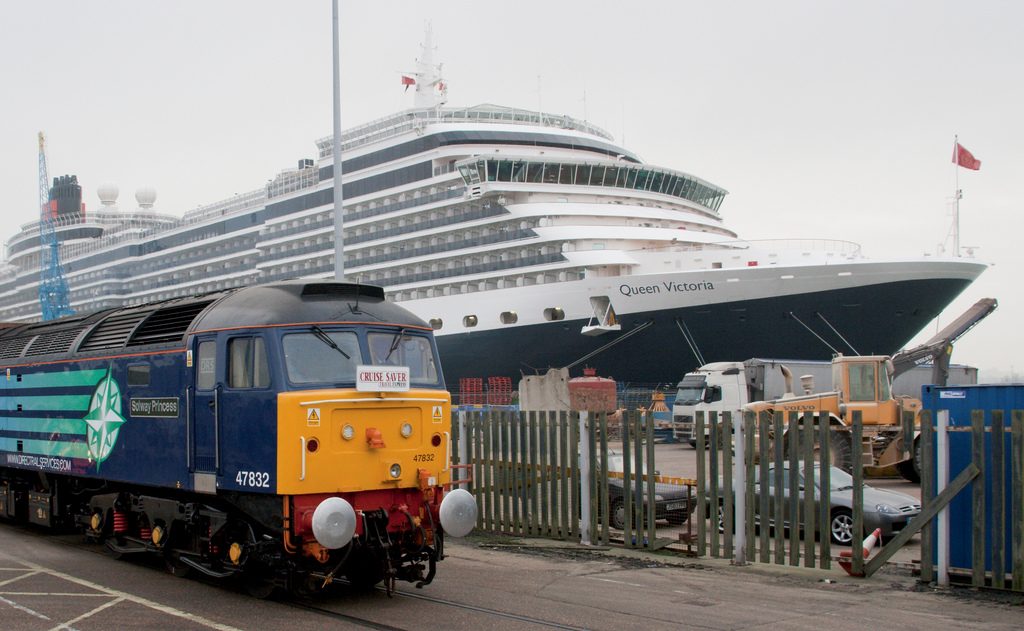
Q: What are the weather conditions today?
A: It is cloudy.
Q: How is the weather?
A: It is cloudy.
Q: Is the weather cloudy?
A: Yes, it is cloudy.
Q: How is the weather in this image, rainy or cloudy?
A: It is cloudy.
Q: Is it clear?
A: No, it is cloudy.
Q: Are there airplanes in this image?
A: No, there are no airplanes.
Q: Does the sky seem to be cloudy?
A: Yes, the sky is cloudy.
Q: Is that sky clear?
A: No, the sky is cloudy.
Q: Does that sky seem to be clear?
A: No, the sky is cloudy.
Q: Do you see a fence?
A: Yes, there is a fence.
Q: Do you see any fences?
A: Yes, there is a fence.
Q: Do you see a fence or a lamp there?
A: Yes, there is a fence.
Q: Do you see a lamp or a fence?
A: Yes, there is a fence.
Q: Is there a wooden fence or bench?
A: Yes, there is a wood fence.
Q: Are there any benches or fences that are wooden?
A: Yes, the fence is wooden.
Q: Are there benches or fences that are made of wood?
A: Yes, the fence is made of wood.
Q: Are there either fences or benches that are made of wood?
A: Yes, the fence is made of wood.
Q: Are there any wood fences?
A: Yes, there is a wood fence.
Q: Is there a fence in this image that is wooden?
A: Yes, there is a fence that is wooden.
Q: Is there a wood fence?
A: Yes, there is a fence that is made of wood.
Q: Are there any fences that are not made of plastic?
A: Yes, there is a fence that is made of wood.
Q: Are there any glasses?
A: No, there are no glasses.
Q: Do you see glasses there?
A: No, there are no glasses.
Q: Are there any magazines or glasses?
A: No, there are no glasses or magazines.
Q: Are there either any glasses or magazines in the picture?
A: No, there are no glasses or magazines.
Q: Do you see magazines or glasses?
A: No, there are no glasses or magazines.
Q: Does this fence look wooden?
A: Yes, the fence is wooden.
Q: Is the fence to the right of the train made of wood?
A: Yes, the fence is made of wood.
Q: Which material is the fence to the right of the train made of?
A: The fence is made of wood.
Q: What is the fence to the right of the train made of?
A: The fence is made of wood.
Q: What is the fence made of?
A: The fence is made of wood.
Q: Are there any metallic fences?
A: No, there is a fence but it is wooden.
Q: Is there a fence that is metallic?
A: No, there is a fence but it is wooden.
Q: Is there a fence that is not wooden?
A: No, there is a fence but it is wooden.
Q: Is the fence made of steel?
A: No, the fence is made of wood.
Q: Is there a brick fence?
A: No, there is a fence but it is made of wood.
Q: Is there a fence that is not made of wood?
A: No, there is a fence but it is made of wood.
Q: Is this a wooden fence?
A: Yes, this is a wooden fence.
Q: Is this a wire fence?
A: No, this is a wooden fence.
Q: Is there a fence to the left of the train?
A: No, the fence is to the right of the train.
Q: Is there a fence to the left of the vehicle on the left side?
A: No, the fence is to the right of the train.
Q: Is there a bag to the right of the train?
A: No, there is a fence to the right of the train.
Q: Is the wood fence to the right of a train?
A: Yes, the fence is to the right of a train.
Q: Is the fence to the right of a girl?
A: No, the fence is to the right of a train.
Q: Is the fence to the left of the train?
A: No, the fence is to the right of the train.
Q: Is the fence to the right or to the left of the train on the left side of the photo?
A: The fence is to the right of the train.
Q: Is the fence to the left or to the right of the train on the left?
A: The fence is to the right of the train.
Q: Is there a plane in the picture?
A: No, there are no airplanes.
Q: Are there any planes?
A: No, there are no planes.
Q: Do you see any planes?
A: No, there are no planes.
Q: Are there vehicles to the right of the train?
A: Yes, there is a vehicle to the right of the train.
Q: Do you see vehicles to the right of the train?
A: Yes, there is a vehicle to the right of the train.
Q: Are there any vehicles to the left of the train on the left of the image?
A: No, the vehicle is to the right of the train.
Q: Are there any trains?
A: Yes, there is a train.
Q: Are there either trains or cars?
A: Yes, there is a train.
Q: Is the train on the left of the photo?
A: Yes, the train is on the left of the image.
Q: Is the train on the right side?
A: No, the train is on the left of the image.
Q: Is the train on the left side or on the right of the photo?
A: The train is on the left of the image.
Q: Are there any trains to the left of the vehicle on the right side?
A: Yes, there is a train to the left of the vehicle.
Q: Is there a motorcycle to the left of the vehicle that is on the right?
A: No, there is a train to the left of the vehicle.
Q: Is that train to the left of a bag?
A: No, the train is to the left of the vehicle.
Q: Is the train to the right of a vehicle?
A: No, the train is to the left of a vehicle.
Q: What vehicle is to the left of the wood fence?
A: The vehicle is a train.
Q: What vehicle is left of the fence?
A: The vehicle is a train.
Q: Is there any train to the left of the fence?
A: Yes, there is a train to the left of the fence.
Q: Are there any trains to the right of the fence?
A: No, the train is to the left of the fence.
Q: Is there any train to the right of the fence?
A: No, the train is to the left of the fence.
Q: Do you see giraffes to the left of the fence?
A: No, there is a train to the left of the fence.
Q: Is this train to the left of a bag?
A: No, the train is to the left of the fence.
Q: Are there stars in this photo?
A: Yes, there is a star.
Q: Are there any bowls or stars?
A: Yes, there is a star.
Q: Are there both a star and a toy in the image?
A: No, there is a star but no toys.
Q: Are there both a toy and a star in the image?
A: No, there is a star but no toys.